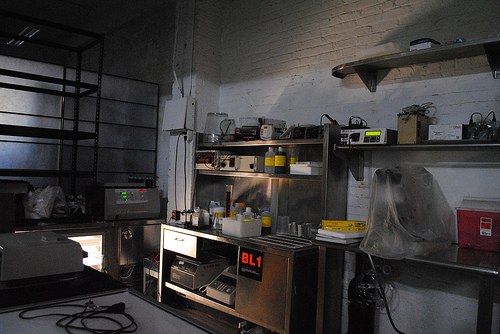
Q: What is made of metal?
A: A table.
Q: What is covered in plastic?
A: A machine.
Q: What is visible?
A: Bottles.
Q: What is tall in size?
A: Tool rack.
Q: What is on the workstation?
A: Items.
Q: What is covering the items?
A: A item covered with a tarp.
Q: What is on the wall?
A: A silver shelf on the wall.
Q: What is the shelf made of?
A: Metal.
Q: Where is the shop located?
A: Garage.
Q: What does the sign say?
A: BL1.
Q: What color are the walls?
A: White.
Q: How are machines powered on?
A: Electricity.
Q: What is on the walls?
A: Shelves.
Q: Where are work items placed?
A: Benches.